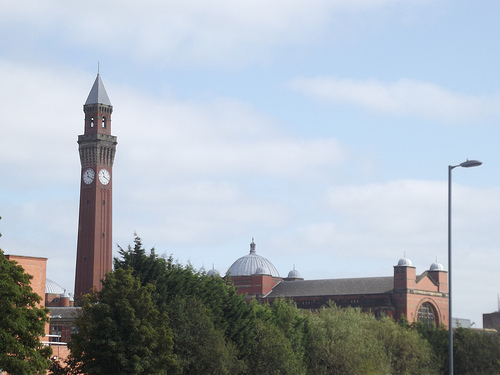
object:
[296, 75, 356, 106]
part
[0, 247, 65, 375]
tree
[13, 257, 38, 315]
part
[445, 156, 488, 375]
post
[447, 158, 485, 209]
part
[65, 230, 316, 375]
bush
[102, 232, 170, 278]
top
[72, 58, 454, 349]
church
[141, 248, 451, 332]
edge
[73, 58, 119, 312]
church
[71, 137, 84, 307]
edge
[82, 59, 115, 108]
tip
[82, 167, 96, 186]
clock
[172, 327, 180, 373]
trees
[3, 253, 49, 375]
wall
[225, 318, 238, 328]
leaves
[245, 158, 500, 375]
street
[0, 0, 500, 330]
sky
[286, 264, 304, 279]
domes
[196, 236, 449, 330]
building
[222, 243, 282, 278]
dome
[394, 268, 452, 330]
brick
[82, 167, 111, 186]
two clocks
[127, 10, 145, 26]
clouds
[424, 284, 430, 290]
bricks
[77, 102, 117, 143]
gazebo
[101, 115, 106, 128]
windows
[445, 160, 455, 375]
pole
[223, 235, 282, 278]
lump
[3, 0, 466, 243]
part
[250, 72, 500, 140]
cloud